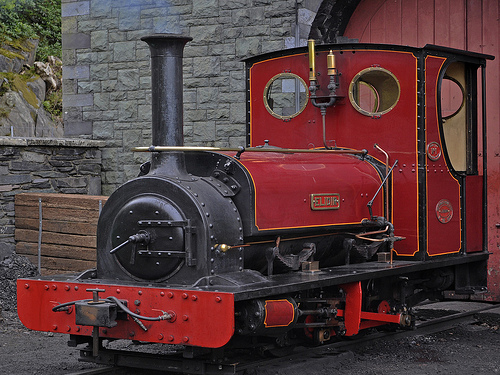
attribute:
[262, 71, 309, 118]
window — round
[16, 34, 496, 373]
train — red, black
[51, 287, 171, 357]
hitch — metal, black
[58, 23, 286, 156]
building — brick, stone, grey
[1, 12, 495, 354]
engine — red, black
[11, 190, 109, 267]
bench — slatted, wooden, brown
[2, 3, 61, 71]
leaves — green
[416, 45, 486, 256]
door — red